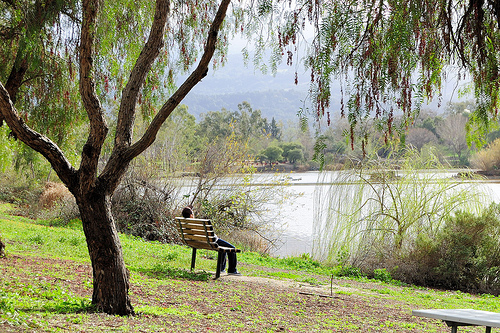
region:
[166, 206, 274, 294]
the guy is on the bench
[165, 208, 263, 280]
the bench is wooden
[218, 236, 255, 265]
the jeans are green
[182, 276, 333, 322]
thre are patches on the ground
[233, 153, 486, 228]
there is water in the park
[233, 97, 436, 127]
there are trees in the background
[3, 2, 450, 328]
the scene is an outdoor scene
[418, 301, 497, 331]
there is a bench in the park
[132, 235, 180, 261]
the grass is green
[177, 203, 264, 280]
the man is looking ate the beach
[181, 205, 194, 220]
the head of a man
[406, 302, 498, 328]
a gray bench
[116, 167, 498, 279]
a calm gray lake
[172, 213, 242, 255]
a brown wooden bench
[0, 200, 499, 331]
a grassy green field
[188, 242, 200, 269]
the black leg of a bench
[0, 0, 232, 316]
a brown tree trunk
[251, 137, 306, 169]
a small row of green trees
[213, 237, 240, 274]
a pair of blue jeans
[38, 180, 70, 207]
a brown bush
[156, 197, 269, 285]
A man on a bench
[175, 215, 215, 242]
The back of a bench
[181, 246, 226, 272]
The legs of a bench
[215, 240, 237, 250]
The seat of a bench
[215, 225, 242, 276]
A persons legs on a bench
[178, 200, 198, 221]
The head of a person on a bench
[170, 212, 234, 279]
A wooden bench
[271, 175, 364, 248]
Water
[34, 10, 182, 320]
A large tree in the grass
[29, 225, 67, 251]
Grass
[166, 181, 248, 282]
a person sitting on a bench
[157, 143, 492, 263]
a body of water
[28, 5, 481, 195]
a tree with long hanging branches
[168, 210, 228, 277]
a wooden bench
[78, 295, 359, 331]
the ground with patches of grass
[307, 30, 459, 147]
brown and green limbs on a tree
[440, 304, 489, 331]
a outdoor table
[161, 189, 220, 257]
a person with brown hair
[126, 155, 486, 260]
several plants along the side of water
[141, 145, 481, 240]
a lake surrounded by trees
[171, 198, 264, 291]
a person relaxing on bench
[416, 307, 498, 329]
a stone bench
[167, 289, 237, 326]
grass sprouts covering the ground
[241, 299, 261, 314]
brown dirt on the ground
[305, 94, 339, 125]
purple blooms on a tree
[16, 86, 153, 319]
a willow tree shading the area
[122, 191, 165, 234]
a thicket of dead branches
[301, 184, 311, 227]
a calm lake surrounded by trees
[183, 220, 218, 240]
wooden slats on the bench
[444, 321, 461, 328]
metal support under the bench